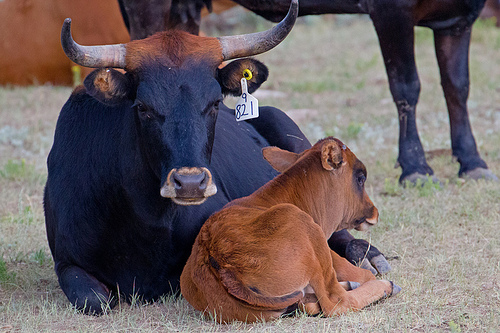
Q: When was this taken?
A: Daytime.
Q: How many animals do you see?
A: Two.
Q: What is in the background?
A: A cow.